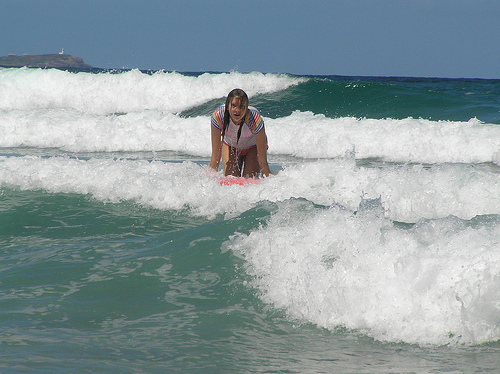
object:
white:
[259, 212, 498, 304]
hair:
[223, 87, 248, 143]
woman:
[201, 87, 280, 184]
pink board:
[208, 176, 263, 187]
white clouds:
[305, 8, 360, 66]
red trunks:
[220, 140, 269, 156]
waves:
[0, 68, 498, 340]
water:
[0, 69, 498, 374]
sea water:
[1, 60, 498, 370]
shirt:
[208, 105, 270, 152]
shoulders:
[242, 107, 268, 133]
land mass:
[0, 51, 93, 69]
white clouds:
[25, 10, 79, 43]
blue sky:
[0, 0, 496, 70]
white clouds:
[57, 16, 103, 73]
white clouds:
[164, 19, 195, 49]